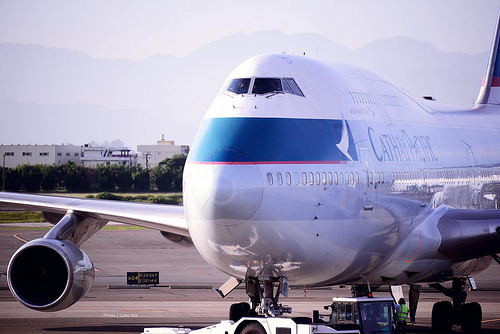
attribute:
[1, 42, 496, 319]
jumbojet — passenger, jetengine, plane, big, white, streamlined, large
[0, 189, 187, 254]
wing — big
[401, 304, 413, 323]
vest — yellow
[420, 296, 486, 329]
wheels — black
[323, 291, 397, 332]
vehicle — truck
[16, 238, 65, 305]
propeller — dark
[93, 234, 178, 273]
road — clean, grey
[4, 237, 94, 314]
engine — jetengine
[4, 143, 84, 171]
building — white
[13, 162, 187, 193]
trees — green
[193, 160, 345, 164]
stripe — red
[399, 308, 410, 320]
safetyvest — green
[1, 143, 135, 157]
buildings — white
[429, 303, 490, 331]
landinggear — rear